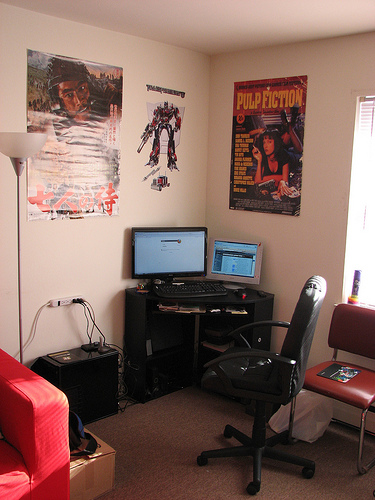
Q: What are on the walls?
A: Posters.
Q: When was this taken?
A: Daytime.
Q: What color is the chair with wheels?
A: Black.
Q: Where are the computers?
A: Desk.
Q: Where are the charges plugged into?
A: Outlet.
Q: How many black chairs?
A: One.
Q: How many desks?
A: One.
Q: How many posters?
A: Three.